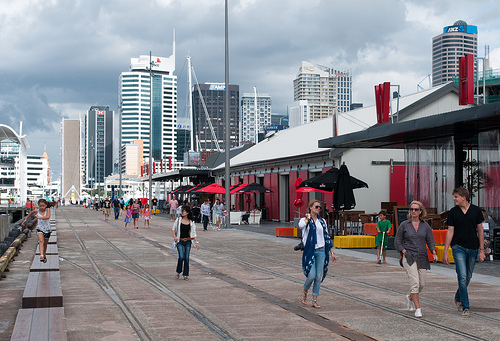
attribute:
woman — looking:
[172, 207, 199, 278]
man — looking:
[445, 188, 490, 316]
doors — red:
[270, 173, 292, 220]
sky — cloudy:
[92, 1, 212, 26]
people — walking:
[80, 198, 98, 211]